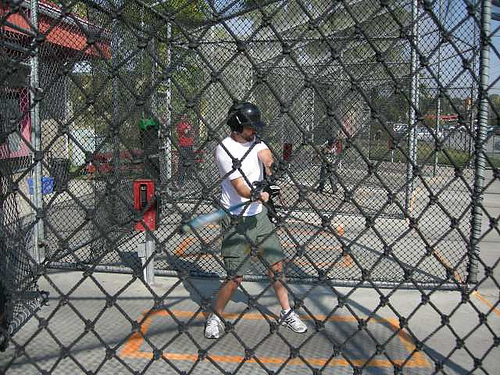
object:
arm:
[254, 142, 275, 170]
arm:
[211, 151, 252, 198]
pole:
[463, 1, 493, 291]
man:
[174, 107, 197, 190]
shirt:
[174, 122, 196, 148]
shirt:
[211, 131, 273, 218]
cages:
[31, 0, 490, 291]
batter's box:
[116, 307, 428, 366]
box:
[131, 177, 156, 234]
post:
[142, 232, 155, 285]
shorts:
[217, 204, 285, 279]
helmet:
[220, 99, 266, 134]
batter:
[201, 99, 306, 341]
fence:
[0, 0, 499, 374]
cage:
[0, 0, 498, 374]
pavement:
[3, 156, 499, 375]